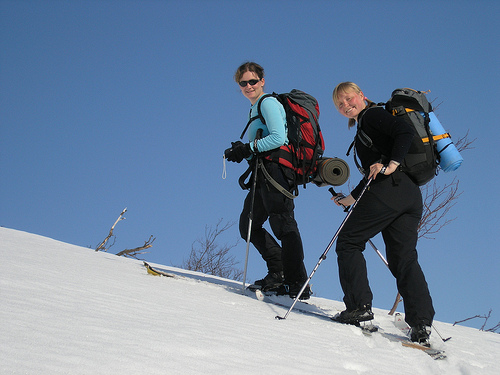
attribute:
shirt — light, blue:
[240, 95, 287, 170]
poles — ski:
[262, 155, 387, 325]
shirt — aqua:
[243, 94, 290, 153]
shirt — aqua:
[353, 105, 425, 190]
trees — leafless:
[180, 230, 232, 286]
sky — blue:
[2, 1, 498, 331]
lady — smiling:
[328, 80, 430, 347]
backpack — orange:
[265, 87, 349, 185]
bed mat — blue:
[404, 84, 476, 179]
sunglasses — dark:
[232, 76, 257, 89]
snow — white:
[92, 327, 157, 359]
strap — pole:
[375, 162, 387, 174]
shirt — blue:
[240, 86, 290, 162]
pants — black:
[242, 160, 310, 296]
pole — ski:
[273, 170, 386, 320]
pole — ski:
[328, 182, 454, 346]